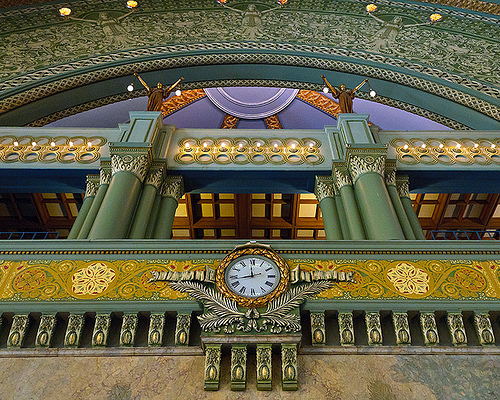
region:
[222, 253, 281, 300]
Round clock with white face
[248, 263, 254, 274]
Black hour hand on clock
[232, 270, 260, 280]
Black minute hand on clock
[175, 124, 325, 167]
Round circle designs on balcony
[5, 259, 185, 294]
Gold trim design on wall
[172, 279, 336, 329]
Sculpted feathers under clock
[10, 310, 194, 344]
Columns on a balcony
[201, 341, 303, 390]
Decorative posts under clock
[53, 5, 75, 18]
Sculpted flower on roof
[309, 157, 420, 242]
Wide green columns supporting balcony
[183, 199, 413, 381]
hands on the clock.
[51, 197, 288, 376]
Designs on the building.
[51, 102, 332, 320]
Columns on the building.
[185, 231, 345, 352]
White face of the clock.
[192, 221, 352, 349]
Black hands on the white clock.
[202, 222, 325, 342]
black roman numerals.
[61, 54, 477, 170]
Ceiling in the building.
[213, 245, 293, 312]
GOLD RIMMED ORNATE CLOCK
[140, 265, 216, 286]
RIBBON BANNER FOR CLOCK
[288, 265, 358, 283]
RIBBON BANNER FOR CLOCK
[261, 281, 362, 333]
PART OF SUPPORT DECORATION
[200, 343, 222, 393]
SUPPORT BRACE FOR CLOCK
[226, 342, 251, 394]
SUPPORT BRACE FOR CLOCK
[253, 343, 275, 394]
SUPPORT BRACE FOR CLOCK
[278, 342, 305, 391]
PART OF SUPPORT BRACE FOR CLOCK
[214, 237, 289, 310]
large white clock face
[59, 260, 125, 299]
design on side of balcony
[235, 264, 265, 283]
black hands on clock face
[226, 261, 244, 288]
roman numerals on clock face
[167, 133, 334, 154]
row of lights on side of building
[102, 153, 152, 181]
small design on green support column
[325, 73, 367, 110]
brown statue on top of pillar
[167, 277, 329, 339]
leaf design below clock face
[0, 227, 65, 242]
blue metal guard rail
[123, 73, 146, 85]
light hanging from statue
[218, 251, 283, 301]
a gold clock on the wall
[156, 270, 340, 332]
small gold feather designs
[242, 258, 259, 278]
the hour hand of a clock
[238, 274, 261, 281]
the long hand of a clock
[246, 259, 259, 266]
the roman numeral for 12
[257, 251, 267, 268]
the roman numeral for one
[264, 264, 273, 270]
the roman numeral for two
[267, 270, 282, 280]
the roman numeral for three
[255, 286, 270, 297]
the roman numeral for five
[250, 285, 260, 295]
the roman numeral for six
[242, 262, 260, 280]
hands on the clock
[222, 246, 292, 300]
gold trim is around clock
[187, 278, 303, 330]
the leaves are golden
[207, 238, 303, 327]
leaves are under the clock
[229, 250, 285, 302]
the clock face is white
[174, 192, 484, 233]
panels are in the ceiling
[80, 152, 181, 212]
gold trim is on the columns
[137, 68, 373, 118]
figures under the arch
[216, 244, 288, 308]
gold frame around clock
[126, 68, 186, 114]
brass statue holding two lights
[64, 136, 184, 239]
thick pillar is green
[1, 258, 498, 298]
decorative trim is gold and green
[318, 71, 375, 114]
brass statue is holding white globe lights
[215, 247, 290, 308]
clock has black Roman numerals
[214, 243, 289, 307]
black hands on clock